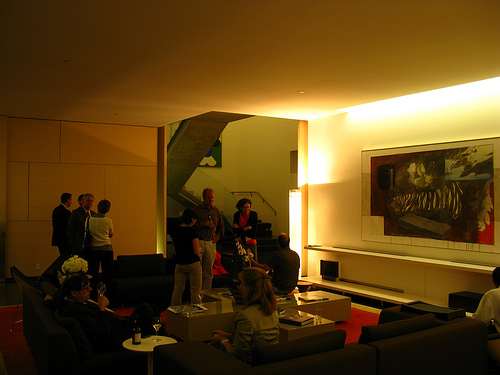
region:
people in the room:
[53, 189, 498, 353]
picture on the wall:
[360, 148, 499, 252]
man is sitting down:
[61, 275, 122, 322]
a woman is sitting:
[211, 265, 277, 353]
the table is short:
[167, 288, 347, 333]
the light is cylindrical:
[290, 186, 301, 280]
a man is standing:
[191, 185, 221, 291]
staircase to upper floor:
[162, 110, 272, 248]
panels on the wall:
[2, 118, 156, 276]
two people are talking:
[75, 193, 113, 273]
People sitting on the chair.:
[56, 229, 289, 349]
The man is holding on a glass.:
[96, 277, 113, 304]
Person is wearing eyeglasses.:
[68, 279, 97, 294]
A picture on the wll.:
[375, 132, 497, 255]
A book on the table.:
[276, 297, 322, 328]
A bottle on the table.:
[123, 306, 150, 346]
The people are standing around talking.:
[153, 172, 273, 276]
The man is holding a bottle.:
[200, 182, 229, 242]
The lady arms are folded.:
[228, 217, 260, 232]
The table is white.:
[266, 270, 367, 342]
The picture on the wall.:
[360, 144, 498, 257]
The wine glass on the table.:
[154, 315, 165, 342]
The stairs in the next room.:
[228, 200, 288, 255]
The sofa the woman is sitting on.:
[154, 313, 489, 373]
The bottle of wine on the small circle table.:
[128, 310, 143, 345]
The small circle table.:
[120, 328, 172, 373]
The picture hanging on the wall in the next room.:
[177, 124, 224, 169]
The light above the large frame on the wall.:
[331, 82, 498, 119]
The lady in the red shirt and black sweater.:
[234, 197, 260, 258]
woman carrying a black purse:
[82, 196, 110, 277]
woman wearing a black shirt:
[168, 203, 214, 305]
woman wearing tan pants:
[159, 205, 210, 300]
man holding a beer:
[190, 188, 229, 295]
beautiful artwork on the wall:
[367, 138, 492, 268]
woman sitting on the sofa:
[209, 253, 292, 372]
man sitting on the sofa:
[52, 270, 124, 345]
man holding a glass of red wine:
[60, 264, 127, 332]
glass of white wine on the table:
[150, 309, 170, 341]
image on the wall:
[333, 126, 497, 236]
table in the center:
[174, 279, 352, 332]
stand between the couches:
[128, 322, 182, 372]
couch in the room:
[156, 314, 488, 369]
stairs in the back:
[198, 178, 280, 248]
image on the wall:
[185, 130, 225, 166]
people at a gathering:
[41, 193, 303, 345]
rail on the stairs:
[236, 185, 281, 212]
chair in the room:
[9, 260, 66, 303]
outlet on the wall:
[28, 247, 43, 279]